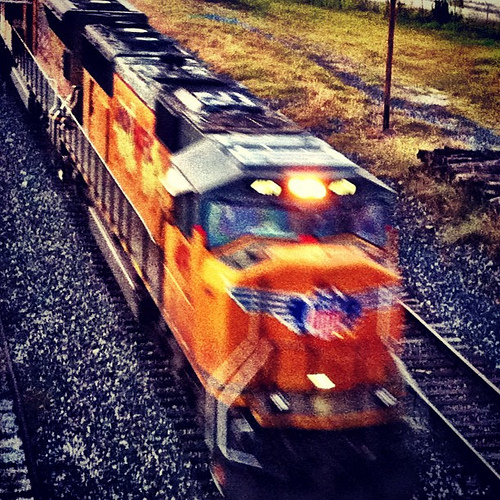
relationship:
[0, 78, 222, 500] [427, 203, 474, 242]
rocks on ground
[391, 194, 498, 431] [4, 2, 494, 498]
rocks on ground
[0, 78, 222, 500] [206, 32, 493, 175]
rocks on ground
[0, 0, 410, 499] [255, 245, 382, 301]
car has engine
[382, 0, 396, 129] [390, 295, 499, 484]
pole near track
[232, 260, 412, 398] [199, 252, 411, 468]
front portion of front engine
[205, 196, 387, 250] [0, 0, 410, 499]
glass of car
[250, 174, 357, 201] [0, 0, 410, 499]
headlight on car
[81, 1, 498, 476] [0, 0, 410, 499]
tracks for car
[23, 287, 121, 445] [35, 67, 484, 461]
rocks near track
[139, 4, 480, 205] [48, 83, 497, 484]
area near track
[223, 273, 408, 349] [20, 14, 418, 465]
image on train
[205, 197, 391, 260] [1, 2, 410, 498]
window on train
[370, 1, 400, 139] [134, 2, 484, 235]
pole on ground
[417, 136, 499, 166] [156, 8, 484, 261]
logs on ground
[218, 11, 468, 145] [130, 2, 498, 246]
trail on grass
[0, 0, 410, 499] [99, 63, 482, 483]
car on tracks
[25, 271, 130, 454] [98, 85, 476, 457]
gravel around tracks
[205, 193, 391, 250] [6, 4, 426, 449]
window on car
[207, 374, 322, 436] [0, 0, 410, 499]
lights on front of car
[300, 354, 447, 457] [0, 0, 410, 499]
lights on front of car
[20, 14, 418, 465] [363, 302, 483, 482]
train running in track